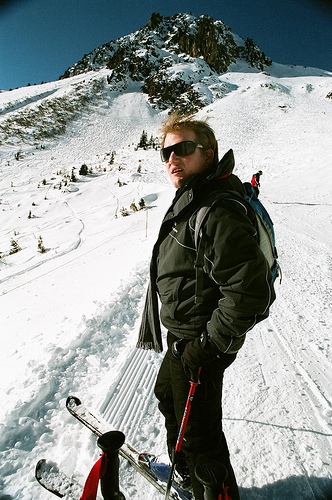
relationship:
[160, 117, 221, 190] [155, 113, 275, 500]
head of man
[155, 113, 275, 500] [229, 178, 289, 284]
man wearing backpack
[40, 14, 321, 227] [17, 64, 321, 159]
mountain has snow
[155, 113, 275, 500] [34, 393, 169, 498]
man standing in skis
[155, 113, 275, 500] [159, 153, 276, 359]
man wearing jacket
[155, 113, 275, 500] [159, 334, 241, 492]
man wearing pants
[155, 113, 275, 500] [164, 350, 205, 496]
man holding pole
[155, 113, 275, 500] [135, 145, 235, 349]
man wearing scarf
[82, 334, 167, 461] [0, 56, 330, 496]
ski tracks in snow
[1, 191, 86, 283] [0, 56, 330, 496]
ski tracks in snow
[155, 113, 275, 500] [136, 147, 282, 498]
man wearing ski gear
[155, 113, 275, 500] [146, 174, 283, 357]
man wears jacket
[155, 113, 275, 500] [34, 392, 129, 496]
man wearing skies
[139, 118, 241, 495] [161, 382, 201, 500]
man holding pole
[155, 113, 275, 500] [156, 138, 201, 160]
man wearing glasses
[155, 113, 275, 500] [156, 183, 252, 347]
man wearing jacket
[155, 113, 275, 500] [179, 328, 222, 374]
man wearing gloves